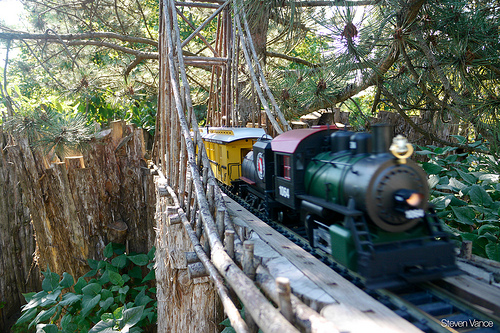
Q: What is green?
A: Plants.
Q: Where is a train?
A: On train tracks.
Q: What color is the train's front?
A: Black.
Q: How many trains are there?
A: One.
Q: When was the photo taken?
A: Daytime.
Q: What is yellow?
A: Back of train.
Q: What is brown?
A: Tree branches.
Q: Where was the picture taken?
A: At the park.